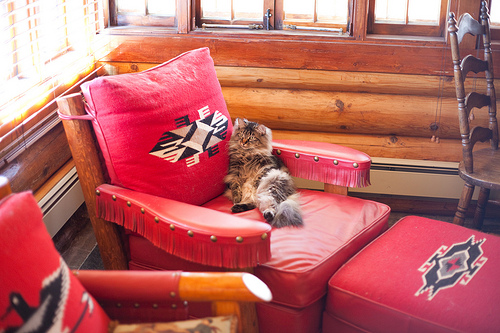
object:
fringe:
[94, 183, 271, 269]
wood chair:
[447, 2, 500, 231]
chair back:
[446, 1, 500, 174]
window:
[0, 0, 105, 105]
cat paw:
[231, 203, 250, 212]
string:
[431, 55, 447, 143]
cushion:
[79, 46, 233, 206]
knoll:
[97, 39, 492, 162]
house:
[0, 0, 500, 333]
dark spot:
[334, 99, 344, 115]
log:
[221, 89, 498, 144]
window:
[375, 0, 440, 26]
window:
[282, 0, 346, 24]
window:
[202, 0, 263, 21]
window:
[123, 2, 175, 16]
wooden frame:
[364, 0, 443, 41]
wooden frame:
[267, 0, 361, 37]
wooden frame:
[182, 0, 272, 36]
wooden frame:
[109, 1, 182, 35]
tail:
[270, 194, 304, 229]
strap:
[57, 109, 94, 120]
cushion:
[0, 189, 111, 331]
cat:
[224, 116, 305, 229]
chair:
[54, 90, 390, 333]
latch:
[265, 9, 273, 30]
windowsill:
[196, 5, 266, 38]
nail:
[96, 190, 100, 195]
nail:
[112, 195, 117, 201]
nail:
[127, 201, 131, 207]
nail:
[141, 208, 145, 214]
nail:
[154, 217, 159, 224]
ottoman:
[321, 213, 498, 333]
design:
[414, 235, 489, 302]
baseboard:
[294, 163, 479, 206]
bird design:
[1, 257, 94, 333]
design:
[148, 105, 228, 168]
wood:
[257, 62, 464, 147]